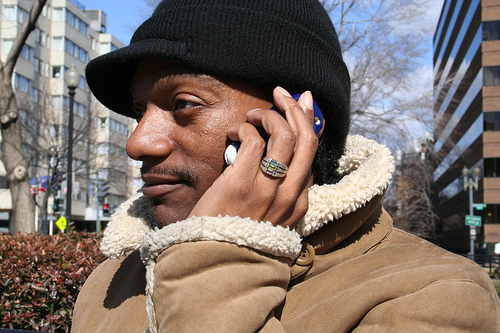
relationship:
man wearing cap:
[72, 0, 500, 333] [84, 0, 351, 154]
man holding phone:
[72, 0, 500, 333] [221, 91, 326, 170]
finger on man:
[241, 102, 296, 194] [72, 0, 500, 333]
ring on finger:
[259, 155, 286, 180] [241, 102, 296, 194]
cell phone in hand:
[219, 94, 327, 167] [185, 86, 320, 236]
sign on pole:
[462, 210, 485, 227] [460, 159, 483, 256]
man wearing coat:
[72, 0, 500, 333] [73, 134, 498, 330]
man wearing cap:
[72, 0, 500, 333] [84, 0, 354, 142]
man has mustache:
[72, 0, 500, 333] [139, 163, 199, 182]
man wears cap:
[72, 0, 500, 333] [84, 0, 351, 154]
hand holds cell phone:
[172, 81, 332, 236] [222, 84, 327, 167]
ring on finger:
[259, 155, 286, 180] [271, 82, 318, 220]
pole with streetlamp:
[63, 92, 76, 235] [62, 67, 82, 227]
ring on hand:
[259, 158, 288, 178] [186, 82, 326, 228]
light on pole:
[462, 164, 471, 179] [459, 164, 484, 262]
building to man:
[0, 1, 152, 238] [72, 0, 500, 333]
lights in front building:
[88, 174, 109, 225] [0, 1, 142, 219]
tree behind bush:
[0, 3, 68, 233] [6, 235, 64, 328]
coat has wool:
[73, 134, 498, 330] [313, 141, 392, 215]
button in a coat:
[294, 238, 319, 268] [73, 134, 498, 330]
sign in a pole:
[55, 215, 70, 235] [61, 235, 63, 237]